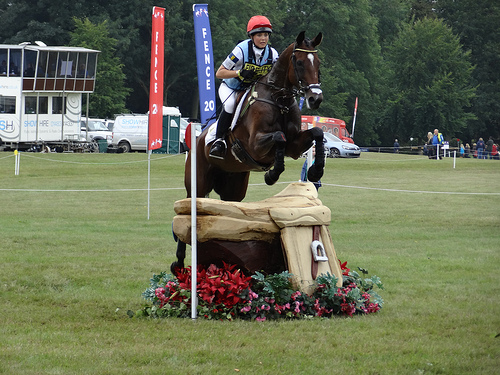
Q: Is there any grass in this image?
A: Yes, there is grass.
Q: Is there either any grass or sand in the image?
A: Yes, there is grass.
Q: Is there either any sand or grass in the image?
A: Yes, there is grass.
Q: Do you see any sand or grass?
A: Yes, there is grass.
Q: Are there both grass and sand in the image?
A: No, there is grass but no sand.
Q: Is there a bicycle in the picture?
A: No, there are no bicycles.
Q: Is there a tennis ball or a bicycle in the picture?
A: No, there are no bicycles or tennis balls.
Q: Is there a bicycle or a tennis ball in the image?
A: No, there are no bicycles or tennis balls.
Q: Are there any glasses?
A: No, there are no glasses.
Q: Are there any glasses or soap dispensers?
A: No, there are no glasses or soap dispensers.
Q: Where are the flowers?
A: The flowers are on the grass.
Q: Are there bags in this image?
A: No, there are no bags.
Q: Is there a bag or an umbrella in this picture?
A: No, there are no bags or umbrellas.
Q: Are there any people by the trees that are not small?
A: Yes, there are people by the trees.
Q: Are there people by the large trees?
A: Yes, there are people by the trees.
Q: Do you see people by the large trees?
A: Yes, there are people by the trees.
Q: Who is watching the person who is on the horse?
A: The people are watching the woman.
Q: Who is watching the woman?
A: The people are watching the woman.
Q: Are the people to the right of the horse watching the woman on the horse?
A: Yes, the people are watching the woman.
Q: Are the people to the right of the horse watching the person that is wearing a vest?
A: Yes, the people are watching the woman.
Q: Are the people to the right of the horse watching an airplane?
A: No, the people are watching the woman.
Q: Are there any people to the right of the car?
A: Yes, there are people to the right of the car.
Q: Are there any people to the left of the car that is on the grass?
A: No, the people are to the right of the car.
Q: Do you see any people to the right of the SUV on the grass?
A: Yes, there are people to the right of the SUV.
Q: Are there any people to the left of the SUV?
A: No, the people are to the right of the SUV.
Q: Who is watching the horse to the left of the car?
A: The people are watching the horse.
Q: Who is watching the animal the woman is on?
A: The people are watching the horse.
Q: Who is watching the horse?
A: The people are watching the horse.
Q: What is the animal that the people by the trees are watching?
A: The animal is a horse.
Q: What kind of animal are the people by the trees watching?
A: The people are watching the horse.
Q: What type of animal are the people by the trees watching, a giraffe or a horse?
A: The people are watching a horse.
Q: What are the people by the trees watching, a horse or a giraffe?
A: The people are watching a horse.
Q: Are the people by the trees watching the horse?
A: Yes, the people are watching the horse.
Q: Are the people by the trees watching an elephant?
A: No, the people are watching the horse.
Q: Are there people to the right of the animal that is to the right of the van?
A: Yes, there are people to the right of the horse.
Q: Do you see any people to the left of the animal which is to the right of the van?
A: No, the people are to the right of the horse.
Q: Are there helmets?
A: Yes, there is a helmet.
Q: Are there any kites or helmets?
A: Yes, there is a helmet.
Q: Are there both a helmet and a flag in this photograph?
A: Yes, there are both a helmet and a flag.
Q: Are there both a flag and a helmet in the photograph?
A: Yes, there are both a helmet and a flag.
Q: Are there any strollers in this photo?
A: No, there are no strollers.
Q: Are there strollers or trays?
A: No, there are no strollers or trays.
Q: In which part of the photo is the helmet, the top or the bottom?
A: The helmet is in the top of the image.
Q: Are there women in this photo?
A: Yes, there is a woman.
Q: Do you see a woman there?
A: Yes, there is a woman.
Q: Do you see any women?
A: Yes, there is a woman.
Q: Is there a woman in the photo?
A: Yes, there is a woman.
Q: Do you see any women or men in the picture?
A: Yes, there is a woman.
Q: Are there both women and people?
A: Yes, there are both a woman and people.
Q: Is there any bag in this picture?
A: No, there are no bags.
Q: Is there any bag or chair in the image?
A: No, there are no bags or chairs.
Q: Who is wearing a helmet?
A: The woman is wearing a helmet.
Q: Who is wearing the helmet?
A: The woman is wearing a helmet.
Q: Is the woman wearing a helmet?
A: Yes, the woman is wearing a helmet.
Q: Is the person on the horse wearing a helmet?
A: Yes, the woman is wearing a helmet.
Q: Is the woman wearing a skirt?
A: No, the woman is wearing a helmet.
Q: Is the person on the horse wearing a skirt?
A: No, the woman is wearing a helmet.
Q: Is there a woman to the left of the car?
A: Yes, there is a woman to the left of the car.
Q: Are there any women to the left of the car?
A: Yes, there is a woman to the left of the car.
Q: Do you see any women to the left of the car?
A: Yes, there is a woman to the left of the car.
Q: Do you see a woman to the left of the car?
A: Yes, there is a woman to the left of the car.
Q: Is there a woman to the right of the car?
A: No, the woman is to the left of the car.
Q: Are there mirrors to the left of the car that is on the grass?
A: No, there is a woman to the left of the car.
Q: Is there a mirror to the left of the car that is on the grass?
A: No, there is a woman to the left of the car.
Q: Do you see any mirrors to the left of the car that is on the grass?
A: No, there is a woman to the left of the car.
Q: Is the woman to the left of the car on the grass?
A: Yes, the woman is to the left of the car.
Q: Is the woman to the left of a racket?
A: No, the woman is to the left of the car.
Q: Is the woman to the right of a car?
A: No, the woman is to the left of a car.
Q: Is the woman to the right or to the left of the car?
A: The woman is to the left of the car.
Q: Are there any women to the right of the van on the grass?
A: Yes, there is a woman to the right of the van.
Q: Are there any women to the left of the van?
A: No, the woman is to the right of the van.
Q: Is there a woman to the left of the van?
A: No, the woman is to the right of the van.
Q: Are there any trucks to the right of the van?
A: No, there is a woman to the right of the van.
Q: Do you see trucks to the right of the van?
A: No, there is a woman to the right of the van.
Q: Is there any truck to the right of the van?
A: No, there is a woman to the right of the van.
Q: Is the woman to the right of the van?
A: Yes, the woman is to the right of the van.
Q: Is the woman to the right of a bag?
A: No, the woman is to the right of the van.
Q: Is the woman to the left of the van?
A: No, the woman is to the right of the van.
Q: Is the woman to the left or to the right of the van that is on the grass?
A: The woman is to the right of the van.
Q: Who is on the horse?
A: The woman is on the horse.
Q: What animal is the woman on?
A: The woman is on the horse.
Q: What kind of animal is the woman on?
A: The woman is on the horse.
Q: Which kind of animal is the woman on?
A: The woman is on the horse.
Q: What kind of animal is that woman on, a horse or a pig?
A: The woman is on a horse.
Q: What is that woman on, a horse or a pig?
A: The woman is on a horse.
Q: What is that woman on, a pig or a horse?
A: The woman is on a horse.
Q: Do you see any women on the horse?
A: Yes, there is a woman on the horse.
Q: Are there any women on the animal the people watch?
A: Yes, there is a woman on the horse.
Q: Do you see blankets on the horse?
A: No, there is a woman on the horse.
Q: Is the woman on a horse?
A: Yes, the woman is on a horse.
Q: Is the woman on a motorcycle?
A: No, the woman is on a horse.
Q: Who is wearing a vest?
A: The woman is wearing a vest.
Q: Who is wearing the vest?
A: The woman is wearing a vest.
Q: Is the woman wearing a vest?
A: Yes, the woman is wearing a vest.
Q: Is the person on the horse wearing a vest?
A: Yes, the woman is wearing a vest.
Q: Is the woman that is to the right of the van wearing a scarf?
A: No, the woman is wearing a vest.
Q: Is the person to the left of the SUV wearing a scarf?
A: No, the woman is wearing a vest.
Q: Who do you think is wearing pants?
A: The woman is wearing pants.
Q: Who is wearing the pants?
A: The woman is wearing pants.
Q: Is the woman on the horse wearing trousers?
A: Yes, the woman is wearing trousers.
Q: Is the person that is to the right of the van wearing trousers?
A: Yes, the woman is wearing trousers.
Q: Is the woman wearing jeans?
A: No, the woman is wearing trousers.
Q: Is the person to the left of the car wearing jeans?
A: No, the woman is wearing trousers.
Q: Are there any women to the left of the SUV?
A: Yes, there is a woman to the left of the SUV.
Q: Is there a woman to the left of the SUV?
A: Yes, there is a woman to the left of the SUV.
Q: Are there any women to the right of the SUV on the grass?
A: No, the woman is to the left of the SUV.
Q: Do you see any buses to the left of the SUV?
A: No, there is a woman to the left of the SUV.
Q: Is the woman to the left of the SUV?
A: Yes, the woman is to the left of the SUV.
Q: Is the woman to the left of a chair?
A: No, the woman is to the left of the SUV.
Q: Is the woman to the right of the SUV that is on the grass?
A: No, the woman is to the left of the SUV.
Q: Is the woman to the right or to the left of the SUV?
A: The woman is to the left of the SUV.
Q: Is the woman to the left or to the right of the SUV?
A: The woman is to the left of the SUV.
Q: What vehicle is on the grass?
A: The vehicle is a SUV.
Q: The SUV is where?
A: The SUV is on the grass.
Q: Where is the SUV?
A: The SUV is on the grass.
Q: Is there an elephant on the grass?
A: No, there is a SUV on the grass.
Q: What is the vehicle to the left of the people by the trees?
A: The vehicle is a SUV.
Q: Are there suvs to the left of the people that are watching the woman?
A: Yes, there is a SUV to the left of the people.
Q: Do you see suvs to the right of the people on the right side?
A: No, the SUV is to the left of the people.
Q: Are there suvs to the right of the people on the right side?
A: No, the SUV is to the left of the people.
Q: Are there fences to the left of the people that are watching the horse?
A: No, there is a SUV to the left of the people.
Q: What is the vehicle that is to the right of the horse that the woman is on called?
A: The vehicle is a SUV.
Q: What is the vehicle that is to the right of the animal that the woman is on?
A: The vehicle is a SUV.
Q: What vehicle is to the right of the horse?
A: The vehicle is a SUV.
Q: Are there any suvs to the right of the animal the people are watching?
A: Yes, there is a SUV to the right of the horse.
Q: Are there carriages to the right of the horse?
A: No, there is a SUV to the right of the horse.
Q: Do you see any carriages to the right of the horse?
A: No, there is a SUV to the right of the horse.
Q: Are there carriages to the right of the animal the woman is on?
A: No, there is a SUV to the right of the horse.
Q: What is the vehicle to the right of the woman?
A: The vehicle is a SUV.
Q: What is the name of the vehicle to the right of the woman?
A: The vehicle is a SUV.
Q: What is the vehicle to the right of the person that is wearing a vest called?
A: The vehicle is a SUV.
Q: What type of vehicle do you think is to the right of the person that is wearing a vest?
A: The vehicle is a SUV.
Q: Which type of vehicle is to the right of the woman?
A: The vehicle is a SUV.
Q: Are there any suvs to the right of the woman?
A: Yes, there is a SUV to the right of the woman.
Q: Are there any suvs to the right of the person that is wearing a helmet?
A: Yes, there is a SUV to the right of the woman.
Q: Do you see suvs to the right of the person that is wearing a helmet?
A: Yes, there is a SUV to the right of the woman.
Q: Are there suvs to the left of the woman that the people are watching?
A: No, the SUV is to the right of the woman.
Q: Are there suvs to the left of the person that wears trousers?
A: No, the SUV is to the right of the woman.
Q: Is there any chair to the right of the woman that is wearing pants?
A: No, there is a SUV to the right of the woman.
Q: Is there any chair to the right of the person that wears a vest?
A: No, there is a SUV to the right of the woman.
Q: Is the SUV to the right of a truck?
A: No, the SUV is to the right of the woman.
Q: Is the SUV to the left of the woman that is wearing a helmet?
A: No, the SUV is to the right of the woman.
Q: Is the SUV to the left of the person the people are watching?
A: No, the SUV is to the right of the woman.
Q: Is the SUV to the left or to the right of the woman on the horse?
A: The SUV is to the right of the woman.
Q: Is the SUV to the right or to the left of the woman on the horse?
A: The SUV is to the right of the woman.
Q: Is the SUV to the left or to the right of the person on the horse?
A: The SUV is to the right of the woman.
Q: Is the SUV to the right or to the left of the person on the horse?
A: The SUV is to the right of the woman.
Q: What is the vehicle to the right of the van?
A: The vehicle is a SUV.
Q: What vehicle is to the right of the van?
A: The vehicle is a SUV.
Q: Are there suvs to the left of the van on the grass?
A: No, the SUV is to the right of the van.